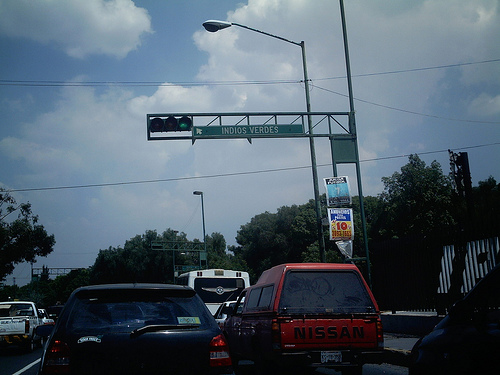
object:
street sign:
[194, 124, 304, 135]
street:
[3, 358, 66, 375]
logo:
[294, 326, 365, 339]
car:
[220, 263, 383, 374]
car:
[41, 286, 228, 372]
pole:
[333, 163, 338, 176]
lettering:
[437, 245, 497, 297]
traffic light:
[149, 116, 192, 132]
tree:
[367, 152, 456, 300]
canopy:
[257, 263, 357, 284]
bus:
[175, 269, 249, 328]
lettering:
[222, 125, 280, 134]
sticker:
[178, 316, 202, 324]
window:
[75, 297, 206, 329]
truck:
[0, 301, 42, 348]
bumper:
[1, 334, 28, 342]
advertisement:
[323, 176, 352, 209]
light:
[176, 116, 192, 132]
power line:
[62, 164, 318, 191]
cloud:
[18, 9, 146, 54]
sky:
[152, 18, 190, 71]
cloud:
[370, 12, 483, 70]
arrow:
[195, 128, 202, 135]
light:
[201, 20, 230, 33]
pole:
[234, 25, 302, 47]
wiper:
[132, 325, 200, 335]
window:
[284, 270, 375, 317]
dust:
[293, 299, 302, 308]